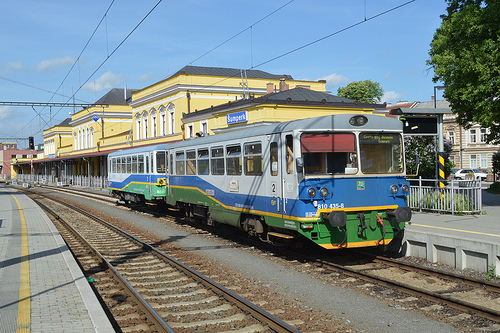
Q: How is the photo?
A: Clear.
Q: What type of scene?
A: Outdoor.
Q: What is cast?
A: Shadow.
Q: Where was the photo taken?
A: Railway.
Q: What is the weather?
A: Sunny.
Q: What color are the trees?
A: Green.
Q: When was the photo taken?
A: Daytime.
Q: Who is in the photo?
A: No one.